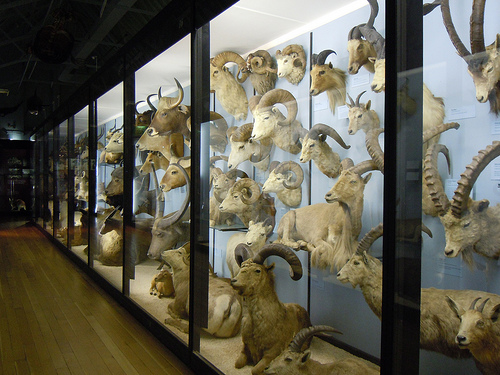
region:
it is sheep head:
[259, 160, 304, 205]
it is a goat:
[277, 163, 374, 267]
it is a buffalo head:
[147, 161, 192, 264]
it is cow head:
[147, 78, 190, 145]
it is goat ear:
[438, 287, 463, 322]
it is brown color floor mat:
[7, 236, 67, 374]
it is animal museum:
[45, 1, 497, 373]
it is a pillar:
[182, 23, 215, 355]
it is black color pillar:
[383, 1, 438, 373]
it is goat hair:
[327, 80, 346, 115]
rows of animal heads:
[48, 3, 496, 360]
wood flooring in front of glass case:
[5, 226, 196, 373]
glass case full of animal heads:
[23, 0, 497, 372]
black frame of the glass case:
[22, 0, 434, 373]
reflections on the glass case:
[202, 65, 377, 333]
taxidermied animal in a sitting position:
[275, 165, 370, 274]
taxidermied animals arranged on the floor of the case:
[49, 198, 326, 373]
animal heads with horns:
[86, 1, 498, 364]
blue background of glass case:
[68, 1, 498, 374]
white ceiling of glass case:
[50, 1, 338, 141]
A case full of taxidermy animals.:
[44, 60, 499, 370]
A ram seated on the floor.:
[225, 245, 315, 360]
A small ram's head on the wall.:
[256, 157, 308, 204]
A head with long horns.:
[136, 163, 192, 259]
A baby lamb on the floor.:
[143, 268, 170, 295]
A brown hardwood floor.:
[43, 280, 98, 337]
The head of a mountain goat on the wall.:
[236, 46, 281, 93]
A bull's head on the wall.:
[145, 81, 200, 144]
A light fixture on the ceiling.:
[31, 20, 79, 62]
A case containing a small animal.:
[6, 172, 28, 214]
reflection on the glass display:
[202, 62, 492, 287]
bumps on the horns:
[451, 145, 498, 216]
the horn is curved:
[250, 242, 305, 284]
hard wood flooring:
[0, 218, 153, 370]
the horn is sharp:
[166, 77, 185, 111]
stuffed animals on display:
[76, 13, 493, 364]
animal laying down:
[161, 243, 245, 340]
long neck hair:
[323, 208, 360, 272]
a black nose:
[456, 334, 469, 341]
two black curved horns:
[311, 48, 338, 66]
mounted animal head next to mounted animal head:
[209, 47, 248, 120]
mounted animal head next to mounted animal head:
[240, 48, 279, 103]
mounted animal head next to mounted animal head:
[276, 44, 308, 86]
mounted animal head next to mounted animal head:
[248, 90, 306, 155]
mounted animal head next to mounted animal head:
[296, 125, 353, 183]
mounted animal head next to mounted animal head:
[341, 88, 381, 136]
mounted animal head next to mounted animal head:
[216, 181, 274, 246]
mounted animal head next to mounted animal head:
[333, 226, 385, 323]